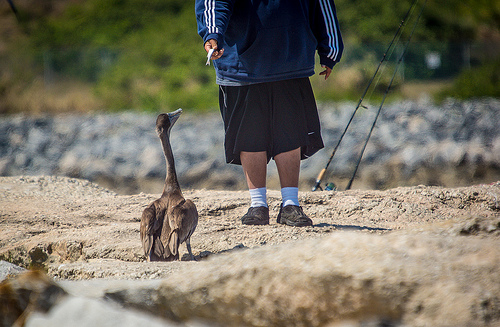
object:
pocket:
[218, 85, 229, 108]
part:
[222, 103, 229, 107]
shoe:
[241, 206, 269, 225]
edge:
[266, 211, 270, 226]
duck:
[139, 108, 198, 263]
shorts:
[218, 77, 323, 166]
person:
[196, 1, 344, 226]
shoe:
[277, 202, 313, 226]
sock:
[281, 187, 300, 208]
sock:
[249, 187, 269, 207]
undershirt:
[216, 76, 310, 87]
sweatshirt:
[193, 1, 343, 87]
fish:
[205, 49, 214, 66]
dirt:
[428, 200, 441, 211]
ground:
[1, 0, 497, 327]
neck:
[157, 132, 182, 193]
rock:
[458, 227, 471, 236]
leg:
[274, 81, 301, 204]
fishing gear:
[311, 0, 426, 192]